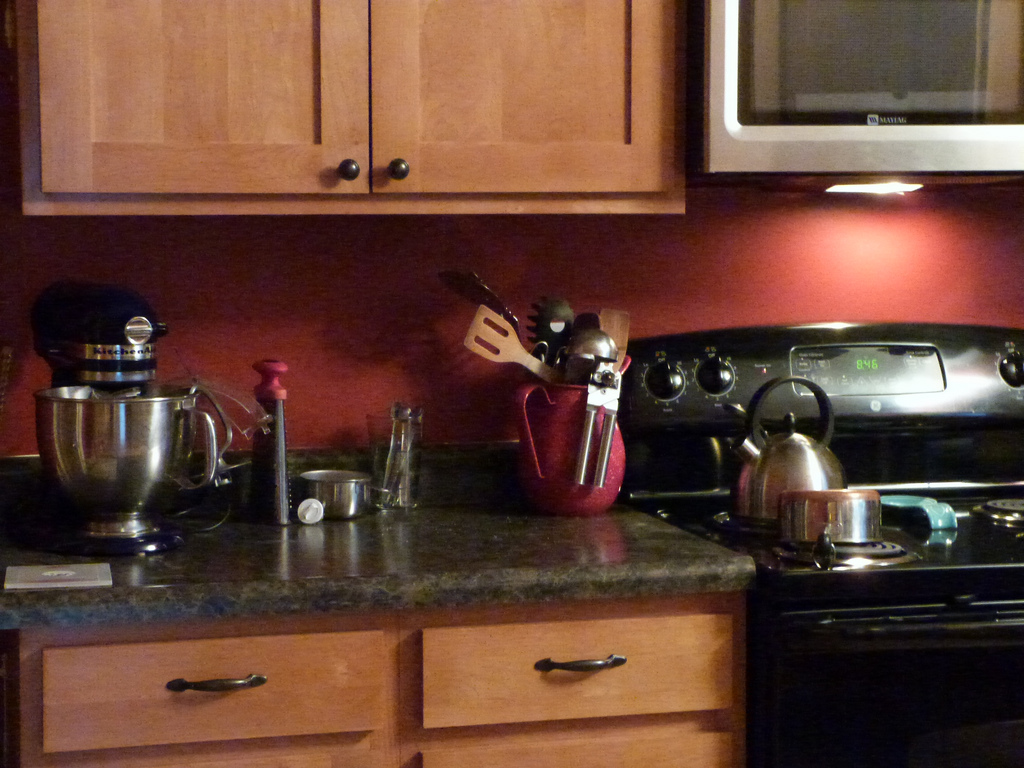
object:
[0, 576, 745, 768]
cabinets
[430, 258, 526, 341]
utensils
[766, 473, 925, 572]
pan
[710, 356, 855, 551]
kettle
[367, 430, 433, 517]
glass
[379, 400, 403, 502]
spoons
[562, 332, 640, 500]
can opener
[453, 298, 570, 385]
spatula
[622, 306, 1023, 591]
stovetop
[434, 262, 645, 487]
server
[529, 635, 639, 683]
handle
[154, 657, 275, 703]
handle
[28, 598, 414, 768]
drawer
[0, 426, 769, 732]
counter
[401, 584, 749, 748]
drawer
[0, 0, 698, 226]
cabinet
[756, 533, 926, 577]
burner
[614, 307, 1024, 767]
stove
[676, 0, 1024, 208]
microwave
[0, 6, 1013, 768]
kitchen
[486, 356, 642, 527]
container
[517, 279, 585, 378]
utensils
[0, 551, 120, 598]
case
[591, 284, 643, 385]
utensils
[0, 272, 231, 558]
bowl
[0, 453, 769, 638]
counter top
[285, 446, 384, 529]
bowl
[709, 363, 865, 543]
tea kettle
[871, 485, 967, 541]
dish